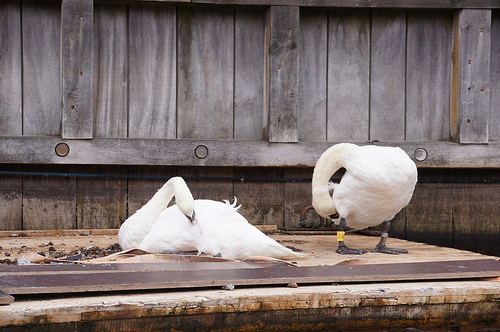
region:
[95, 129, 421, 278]
A pair of swan in captivity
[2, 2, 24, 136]
wooden plank next to wooden plank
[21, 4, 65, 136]
wooden plank next to wooden plank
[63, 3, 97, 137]
wooden plank next to wooden plank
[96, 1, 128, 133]
wooden plank next to wooden plank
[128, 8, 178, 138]
wooden plank next to wooden plank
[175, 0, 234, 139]
wooden plank next to wooden plank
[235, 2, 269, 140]
wooden plank next to wooden plank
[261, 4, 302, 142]
wooden plank next to wooden plank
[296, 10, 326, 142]
wooden plank next to wooden plank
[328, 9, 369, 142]
wooden plank next to wooden plank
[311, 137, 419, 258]
A white goose cleaning itself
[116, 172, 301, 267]
A white goose cleaning itself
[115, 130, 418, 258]
a pair of geese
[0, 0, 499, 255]
A large wooden fence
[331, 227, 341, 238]
a yellow tag on a goose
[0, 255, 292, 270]
A small wooden plank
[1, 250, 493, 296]
A small wooden plank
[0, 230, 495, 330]
a wooden platform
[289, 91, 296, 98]
a rusted nail in some wood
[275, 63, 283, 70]
a rusted nail in some wood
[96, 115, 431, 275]
two swans on a stand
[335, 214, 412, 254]
the legs of a bird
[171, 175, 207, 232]
the head of a bird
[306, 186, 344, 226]
the head of a bird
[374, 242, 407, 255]
the foot of a bird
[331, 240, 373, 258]
the boot of a bird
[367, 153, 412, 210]
the breast of bird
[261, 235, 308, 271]
the tail of a bird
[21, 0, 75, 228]
a panel of wood on a fence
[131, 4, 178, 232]
a panel of wood on a fence